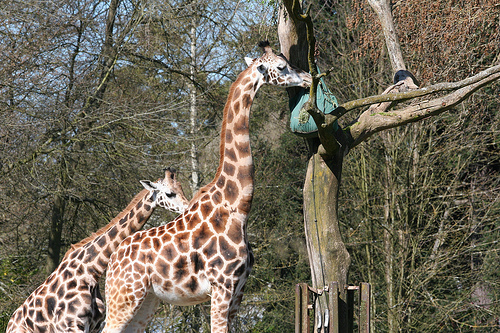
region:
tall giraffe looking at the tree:
[92, 25, 355, 330]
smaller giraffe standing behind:
[6, 162, 196, 327]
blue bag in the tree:
[282, 76, 352, 148]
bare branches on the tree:
[403, 165, 496, 319]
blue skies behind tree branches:
[191, 5, 281, 87]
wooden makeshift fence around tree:
[283, 275, 395, 332]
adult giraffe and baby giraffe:
[4, 35, 321, 331]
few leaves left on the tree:
[347, 0, 492, 73]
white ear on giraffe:
[136, 173, 157, 193]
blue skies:
[23, 53, 88, 122]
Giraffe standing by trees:
[4, 168, 166, 328]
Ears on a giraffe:
[112, 160, 222, 236]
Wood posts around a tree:
[286, 268, 386, 331]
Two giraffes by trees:
[39, 43, 278, 330]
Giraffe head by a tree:
[195, 28, 466, 173]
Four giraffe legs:
[90, 271, 280, 331]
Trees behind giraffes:
[9, 83, 345, 282]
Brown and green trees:
[340, 19, 497, 219]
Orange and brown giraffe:
[112, 223, 304, 331]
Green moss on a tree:
[301, 144, 415, 326]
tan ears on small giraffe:
[128, 173, 158, 201]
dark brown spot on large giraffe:
[193, 225, 209, 244]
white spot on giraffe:
[168, 241, 178, 249]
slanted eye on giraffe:
[276, 61, 291, 73]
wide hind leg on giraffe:
[92, 265, 157, 327]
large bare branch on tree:
[87, 23, 134, 72]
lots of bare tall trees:
[43, 20, 200, 136]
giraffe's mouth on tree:
[291, 64, 323, 98]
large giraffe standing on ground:
[101, 46, 299, 316]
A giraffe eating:
[246, 23, 343, 135]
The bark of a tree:
[278, 158, 375, 254]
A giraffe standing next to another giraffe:
[1, 154, 189, 331]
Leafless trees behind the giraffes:
[2, 0, 187, 162]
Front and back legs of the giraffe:
[101, 297, 236, 332]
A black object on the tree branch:
[391, 64, 418, 86]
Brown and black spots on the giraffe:
[154, 223, 239, 287]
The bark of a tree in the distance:
[187, 28, 202, 180]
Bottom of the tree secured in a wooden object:
[291, 253, 388, 332]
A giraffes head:
[140, 166, 192, 212]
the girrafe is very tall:
[223, 51, 280, 243]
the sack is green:
[281, 78, 338, 128]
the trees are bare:
[28, 77, 158, 152]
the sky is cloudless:
[87, 23, 241, 64]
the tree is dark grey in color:
[304, 178, 354, 283]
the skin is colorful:
[122, 235, 212, 292]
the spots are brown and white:
[149, 247, 225, 276]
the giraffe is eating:
[233, 35, 319, 94]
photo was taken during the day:
[0, 0, 497, 320]